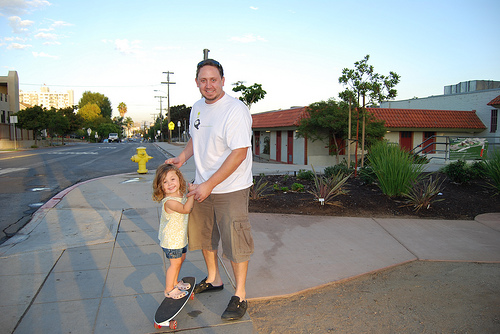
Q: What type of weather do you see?
A: It is sunny.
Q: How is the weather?
A: It is sunny.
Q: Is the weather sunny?
A: Yes, it is sunny.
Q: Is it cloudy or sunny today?
A: It is sunny.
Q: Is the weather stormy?
A: No, it is sunny.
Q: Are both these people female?
A: No, they are both male and female.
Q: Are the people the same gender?
A: No, they are both male and female.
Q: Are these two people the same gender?
A: No, they are both male and female.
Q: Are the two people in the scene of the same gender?
A: No, they are both male and female.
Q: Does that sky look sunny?
A: Yes, the sky is sunny.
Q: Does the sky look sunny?
A: Yes, the sky is sunny.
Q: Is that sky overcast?
A: No, the sky is sunny.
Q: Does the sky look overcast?
A: No, the sky is sunny.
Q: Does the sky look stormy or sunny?
A: The sky is sunny.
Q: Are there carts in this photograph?
A: No, there are no carts.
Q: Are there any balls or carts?
A: No, there are no carts or balls.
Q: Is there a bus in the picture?
A: No, there are no buses.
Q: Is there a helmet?
A: No, there are no helmets.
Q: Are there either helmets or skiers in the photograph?
A: No, there are no helmets or skiers.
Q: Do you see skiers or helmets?
A: No, there are no helmets or skiers.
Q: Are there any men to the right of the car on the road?
A: Yes, there is a man to the right of the car.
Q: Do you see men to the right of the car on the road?
A: Yes, there is a man to the right of the car.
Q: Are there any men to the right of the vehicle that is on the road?
A: Yes, there is a man to the right of the car.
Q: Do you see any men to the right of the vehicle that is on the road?
A: Yes, there is a man to the right of the car.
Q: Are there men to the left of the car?
A: No, the man is to the right of the car.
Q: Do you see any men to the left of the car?
A: No, the man is to the right of the car.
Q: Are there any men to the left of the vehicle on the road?
A: No, the man is to the right of the car.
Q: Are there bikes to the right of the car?
A: No, there is a man to the right of the car.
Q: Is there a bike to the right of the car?
A: No, there is a man to the right of the car.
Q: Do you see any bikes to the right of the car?
A: No, there is a man to the right of the car.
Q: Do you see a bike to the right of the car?
A: No, there is a man to the right of the car.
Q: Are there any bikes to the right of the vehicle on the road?
A: No, there is a man to the right of the car.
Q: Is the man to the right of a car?
A: Yes, the man is to the right of a car.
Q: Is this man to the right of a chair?
A: No, the man is to the right of a car.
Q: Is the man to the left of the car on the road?
A: No, the man is to the right of the car.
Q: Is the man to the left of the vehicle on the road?
A: No, the man is to the right of the car.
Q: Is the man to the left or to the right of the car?
A: The man is to the right of the car.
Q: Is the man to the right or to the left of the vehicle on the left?
A: The man is to the right of the car.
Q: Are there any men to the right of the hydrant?
A: Yes, there is a man to the right of the hydrant.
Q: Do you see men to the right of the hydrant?
A: Yes, there is a man to the right of the hydrant.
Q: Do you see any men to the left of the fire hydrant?
A: No, the man is to the right of the fire hydrant.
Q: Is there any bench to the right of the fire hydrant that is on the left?
A: No, there is a man to the right of the fire hydrant.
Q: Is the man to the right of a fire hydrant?
A: Yes, the man is to the right of a fire hydrant.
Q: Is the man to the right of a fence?
A: No, the man is to the right of a fire hydrant.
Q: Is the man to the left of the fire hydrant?
A: No, the man is to the right of the fire hydrant.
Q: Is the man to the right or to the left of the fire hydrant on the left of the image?
A: The man is to the right of the hydrant.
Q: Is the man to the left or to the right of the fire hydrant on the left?
A: The man is to the right of the hydrant.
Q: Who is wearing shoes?
A: The man is wearing shoes.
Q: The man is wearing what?
A: The man is wearing shoes.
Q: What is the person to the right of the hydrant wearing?
A: The man is wearing shoes.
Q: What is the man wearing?
A: The man is wearing shoes.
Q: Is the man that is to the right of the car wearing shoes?
A: Yes, the man is wearing shoes.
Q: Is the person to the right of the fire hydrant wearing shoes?
A: Yes, the man is wearing shoes.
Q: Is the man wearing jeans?
A: No, the man is wearing shoes.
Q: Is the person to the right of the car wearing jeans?
A: No, the man is wearing shoes.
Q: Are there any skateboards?
A: Yes, there is a skateboard.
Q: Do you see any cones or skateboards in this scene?
A: Yes, there is a skateboard.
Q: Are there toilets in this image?
A: No, there are no toilets.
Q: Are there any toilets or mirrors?
A: No, there are no toilets or mirrors.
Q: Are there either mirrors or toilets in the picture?
A: No, there are no toilets or mirrors.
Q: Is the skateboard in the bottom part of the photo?
A: Yes, the skateboard is in the bottom of the image.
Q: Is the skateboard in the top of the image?
A: No, the skateboard is in the bottom of the image.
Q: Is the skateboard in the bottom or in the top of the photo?
A: The skateboard is in the bottom of the image.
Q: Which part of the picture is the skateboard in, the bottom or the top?
A: The skateboard is in the bottom of the image.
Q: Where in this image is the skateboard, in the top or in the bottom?
A: The skateboard is in the bottom of the image.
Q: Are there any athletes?
A: No, there are no athletes.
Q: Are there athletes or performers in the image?
A: No, there are no athletes or performers.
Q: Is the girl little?
A: Yes, the girl is little.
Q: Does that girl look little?
A: Yes, the girl is little.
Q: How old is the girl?
A: The girl is little.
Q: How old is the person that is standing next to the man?
A: The girl is little.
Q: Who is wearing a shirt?
A: The girl is wearing a shirt.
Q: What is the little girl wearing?
A: The girl is wearing a shirt.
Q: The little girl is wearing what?
A: The girl is wearing a shirt.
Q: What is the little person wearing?
A: The girl is wearing a shirt.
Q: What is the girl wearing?
A: The girl is wearing a shirt.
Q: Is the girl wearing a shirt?
A: Yes, the girl is wearing a shirt.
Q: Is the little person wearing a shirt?
A: Yes, the girl is wearing a shirt.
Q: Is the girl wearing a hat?
A: No, the girl is wearing a shirt.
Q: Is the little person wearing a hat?
A: No, the girl is wearing a shirt.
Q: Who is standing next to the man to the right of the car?
A: The girl is standing next to the man.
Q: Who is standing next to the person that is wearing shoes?
A: The girl is standing next to the man.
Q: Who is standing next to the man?
A: The girl is standing next to the man.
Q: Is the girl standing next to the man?
A: Yes, the girl is standing next to the man.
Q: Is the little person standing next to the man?
A: Yes, the girl is standing next to the man.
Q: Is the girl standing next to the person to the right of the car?
A: Yes, the girl is standing next to the man.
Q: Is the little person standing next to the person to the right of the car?
A: Yes, the girl is standing next to the man.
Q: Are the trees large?
A: Yes, the trees are large.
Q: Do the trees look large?
A: Yes, the trees are large.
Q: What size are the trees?
A: The trees are large.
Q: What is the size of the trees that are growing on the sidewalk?
A: The trees are large.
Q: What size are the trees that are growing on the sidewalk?
A: The trees are large.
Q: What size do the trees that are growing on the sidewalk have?
A: The trees have large size.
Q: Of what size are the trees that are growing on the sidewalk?
A: The trees are large.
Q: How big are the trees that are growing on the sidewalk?
A: The trees are large.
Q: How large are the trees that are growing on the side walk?
A: The trees are large.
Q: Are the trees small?
A: No, the trees are large.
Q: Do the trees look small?
A: No, the trees are large.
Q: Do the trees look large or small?
A: The trees are large.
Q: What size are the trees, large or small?
A: The trees are large.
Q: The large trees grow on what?
A: The trees grow on the sidewalk.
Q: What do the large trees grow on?
A: The trees grow on the sidewalk.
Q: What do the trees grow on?
A: The trees grow on the sidewalk.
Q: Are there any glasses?
A: No, there are no glasses.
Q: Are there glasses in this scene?
A: No, there are no glasses.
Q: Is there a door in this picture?
A: Yes, there are doors.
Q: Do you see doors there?
A: Yes, there are doors.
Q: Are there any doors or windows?
A: Yes, there are doors.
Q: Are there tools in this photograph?
A: No, there are no tools.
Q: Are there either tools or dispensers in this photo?
A: No, there are no tools or dispensers.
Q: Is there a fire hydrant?
A: Yes, there is a fire hydrant.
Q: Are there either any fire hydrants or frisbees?
A: Yes, there is a fire hydrant.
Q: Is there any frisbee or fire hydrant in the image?
A: Yes, there is a fire hydrant.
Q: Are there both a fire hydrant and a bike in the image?
A: No, there is a fire hydrant but no bikes.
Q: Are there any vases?
A: No, there are no vases.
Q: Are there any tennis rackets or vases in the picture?
A: No, there are no vases or tennis rackets.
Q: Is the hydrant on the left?
A: Yes, the hydrant is on the left of the image.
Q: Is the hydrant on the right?
A: No, the hydrant is on the left of the image.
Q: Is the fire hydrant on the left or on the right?
A: The fire hydrant is on the left of the image.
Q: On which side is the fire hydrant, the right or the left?
A: The fire hydrant is on the left of the image.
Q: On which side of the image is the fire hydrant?
A: The fire hydrant is on the left of the image.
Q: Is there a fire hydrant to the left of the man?
A: Yes, there is a fire hydrant to the left of the man.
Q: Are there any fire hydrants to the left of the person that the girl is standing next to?
A: Yes, there is a fire hydrant to the left of the man.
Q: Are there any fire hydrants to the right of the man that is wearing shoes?
A: No, the fire hydrant is to the left of the man.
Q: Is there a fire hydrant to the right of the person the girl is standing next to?
A: No, the fire hydrant is to the left of the man.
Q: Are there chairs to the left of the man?
A: No, there is a fire hydrant to the left of the man.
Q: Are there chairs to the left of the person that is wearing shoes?
A: No, there is a fire hydrant to the left of the man.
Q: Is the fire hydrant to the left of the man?
A: Yes, the fire hydrant is to the left of the man.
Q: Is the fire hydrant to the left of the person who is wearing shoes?
A: Yes, the fire hydrant is to the left of the man.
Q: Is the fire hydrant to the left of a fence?
A: No, the fire hydrant is to the left of the man.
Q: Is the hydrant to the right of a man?
A: No, the hydrant is to the left of a man.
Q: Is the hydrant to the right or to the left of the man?
A: The hydrant is to the left of the man.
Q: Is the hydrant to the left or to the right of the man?
A: The hydrant is to the left of the man.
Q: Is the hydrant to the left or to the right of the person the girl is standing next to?
A: The hydrant is to the left of the man.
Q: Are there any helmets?
A: No, there are no helmets.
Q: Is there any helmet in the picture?
A: No, there are no helmets.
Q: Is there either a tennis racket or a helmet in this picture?
A: No, there are no helmets or rackets.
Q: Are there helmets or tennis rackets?
A: No, there are no helmets or tennis rackets.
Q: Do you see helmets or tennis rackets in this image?
A: No, there are no helmets or tennis rackets.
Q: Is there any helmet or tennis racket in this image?
A: No, there are no helmets or rackets.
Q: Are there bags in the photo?
A: No, there are no bags.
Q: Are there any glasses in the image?
A: No, there are no glasses.